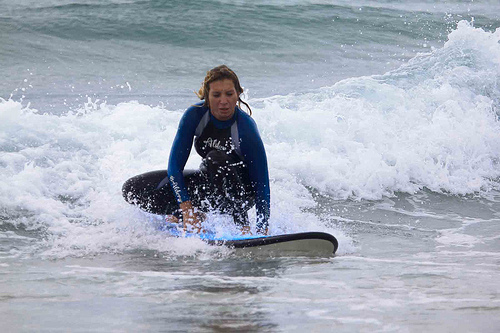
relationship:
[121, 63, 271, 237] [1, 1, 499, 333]
woman on top of ocean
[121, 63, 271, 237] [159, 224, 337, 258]
woman on top of surfboard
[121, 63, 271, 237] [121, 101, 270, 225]
woman wearing wetsuit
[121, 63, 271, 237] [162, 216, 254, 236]
woman has feet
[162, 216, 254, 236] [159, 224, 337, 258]
feet on top of surfboard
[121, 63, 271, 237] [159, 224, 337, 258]
woman riding on surfboard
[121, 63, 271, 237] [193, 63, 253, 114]
woman has hair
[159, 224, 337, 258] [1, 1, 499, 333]
surfboard inside of ocean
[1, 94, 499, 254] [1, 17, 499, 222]
foam on top of wave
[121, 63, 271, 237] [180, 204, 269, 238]
woman has hands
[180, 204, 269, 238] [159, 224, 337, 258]
hands touching surfboard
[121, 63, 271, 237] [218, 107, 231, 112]
woman has mouth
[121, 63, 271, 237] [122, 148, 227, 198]
woman has knees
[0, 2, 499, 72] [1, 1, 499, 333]
ripples on top of ocean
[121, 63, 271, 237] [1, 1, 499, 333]
woman surfing in ocean